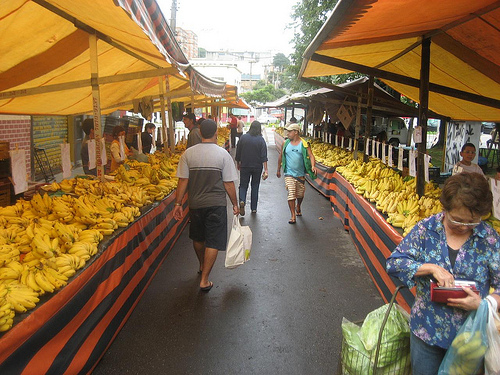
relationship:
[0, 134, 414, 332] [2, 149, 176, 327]
large number of bananas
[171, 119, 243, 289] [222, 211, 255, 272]
man a bag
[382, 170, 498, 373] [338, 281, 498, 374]
woman carrying multiple bags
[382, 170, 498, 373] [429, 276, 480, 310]
woman examines her wallet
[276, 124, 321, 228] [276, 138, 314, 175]
man is wearing a blue shirt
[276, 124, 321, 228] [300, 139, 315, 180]
man is wearing green jacket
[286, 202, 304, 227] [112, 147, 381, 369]
pedestrians feet walking on cement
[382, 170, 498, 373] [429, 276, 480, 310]
woman looking down at her wallet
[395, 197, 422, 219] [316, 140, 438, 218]
bunch of bananas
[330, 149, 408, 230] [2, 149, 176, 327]
bunch of bananas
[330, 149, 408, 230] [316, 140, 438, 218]
bunch of bananas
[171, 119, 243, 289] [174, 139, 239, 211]
man wearing gray shirt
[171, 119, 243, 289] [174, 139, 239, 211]
man two toned gray shirt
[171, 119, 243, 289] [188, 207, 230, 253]
man colored dark pants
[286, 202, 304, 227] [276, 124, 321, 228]
slippers on man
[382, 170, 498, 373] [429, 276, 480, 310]
woman lookin in red wallet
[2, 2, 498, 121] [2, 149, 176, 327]
canopies over bananas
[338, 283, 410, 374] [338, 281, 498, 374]
cart full of shopping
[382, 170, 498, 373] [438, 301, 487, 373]
woman with a bag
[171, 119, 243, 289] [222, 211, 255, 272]
man with a shopping bag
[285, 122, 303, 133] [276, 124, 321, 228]
ballcap on man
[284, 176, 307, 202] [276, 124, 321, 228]
striped shorts on man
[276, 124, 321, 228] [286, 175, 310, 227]
man in shorts walking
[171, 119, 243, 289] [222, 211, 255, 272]
man a white bag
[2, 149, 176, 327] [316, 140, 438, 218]
bananas that are yellow on a shelf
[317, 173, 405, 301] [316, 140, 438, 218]
black and red table cloth with bananas on top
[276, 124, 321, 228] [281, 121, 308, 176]
man walking with a hat and blue shirt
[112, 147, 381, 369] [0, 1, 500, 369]
path of cement inside produce stand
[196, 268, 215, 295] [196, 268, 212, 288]
sandals on feet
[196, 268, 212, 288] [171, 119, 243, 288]
feet of man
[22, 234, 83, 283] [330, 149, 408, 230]
bananas in bunch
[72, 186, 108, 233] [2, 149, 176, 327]
bananas in bunch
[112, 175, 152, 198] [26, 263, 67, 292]
bananas in bunch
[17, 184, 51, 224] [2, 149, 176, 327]
bananas in bunches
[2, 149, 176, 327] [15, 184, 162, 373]
bananas on table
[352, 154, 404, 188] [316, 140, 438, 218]
bananas on right table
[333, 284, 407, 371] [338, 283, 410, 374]
packages in push basket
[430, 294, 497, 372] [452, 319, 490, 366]
bag has bananas